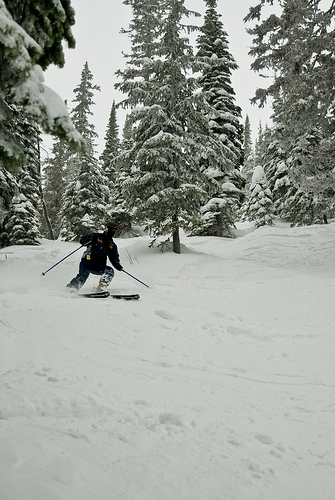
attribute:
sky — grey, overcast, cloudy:
[34, 0, 316, 149]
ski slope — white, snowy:
[1, 218, 334, 497]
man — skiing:
[65, 221, 123, 297]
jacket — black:
[81, 235, 122, 268]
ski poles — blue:
[36, 234, 154, 289]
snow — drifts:
[60, 314, 216, 377]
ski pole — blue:
[41, 239, 91, 275]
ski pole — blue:
[118, 268, 150, 288]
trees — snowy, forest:
[131, 27, 230, 164]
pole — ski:
[41, 242, 88, 278]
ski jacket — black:
[78, 234, 122, 271]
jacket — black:
[76, 233, 119, 267]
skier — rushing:
[65, 225, 135, 304]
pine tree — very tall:
[124, 0, 203, 256]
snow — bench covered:
[205, 246, 287, 326]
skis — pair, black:
[79, 290, 140, 300]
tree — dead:
[115, 0, 249, 255]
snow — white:
[167, 241, 289, 300]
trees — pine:
[239, 3, 324, 226]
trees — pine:
[112, 1, 249, 244]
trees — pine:
[50, 62, 131, 234]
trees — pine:
[0, 5, 58, 246]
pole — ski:
[116, 263, 154, 291]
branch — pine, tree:
[192, 105, 228, 151]